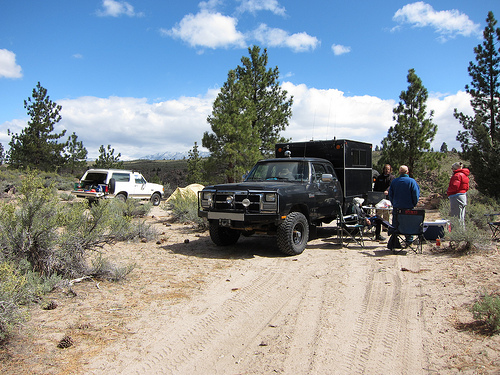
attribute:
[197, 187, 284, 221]
rack — metal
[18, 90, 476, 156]
clouds — white ,  background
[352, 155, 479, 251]
people — four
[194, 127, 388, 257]
truck — black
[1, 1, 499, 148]
clouds — white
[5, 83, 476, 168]
cloud — white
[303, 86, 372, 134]
clouds — white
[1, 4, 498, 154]
sky — blue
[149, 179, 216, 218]
tent — yellow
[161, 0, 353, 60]
clouds — white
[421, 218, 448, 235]
cooler — blue  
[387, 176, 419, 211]
jacket — blue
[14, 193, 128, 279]
bushes — dried and bare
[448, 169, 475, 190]
coats — outdoors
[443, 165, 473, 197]
jacket — red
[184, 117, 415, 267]
truck — black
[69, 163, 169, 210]
truck — white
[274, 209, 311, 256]
wheel —  front 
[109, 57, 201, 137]
clouds — white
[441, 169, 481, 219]
coat — red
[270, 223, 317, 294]
tread — thick and black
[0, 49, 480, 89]
sky — blue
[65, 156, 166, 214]
stuff —  camping 